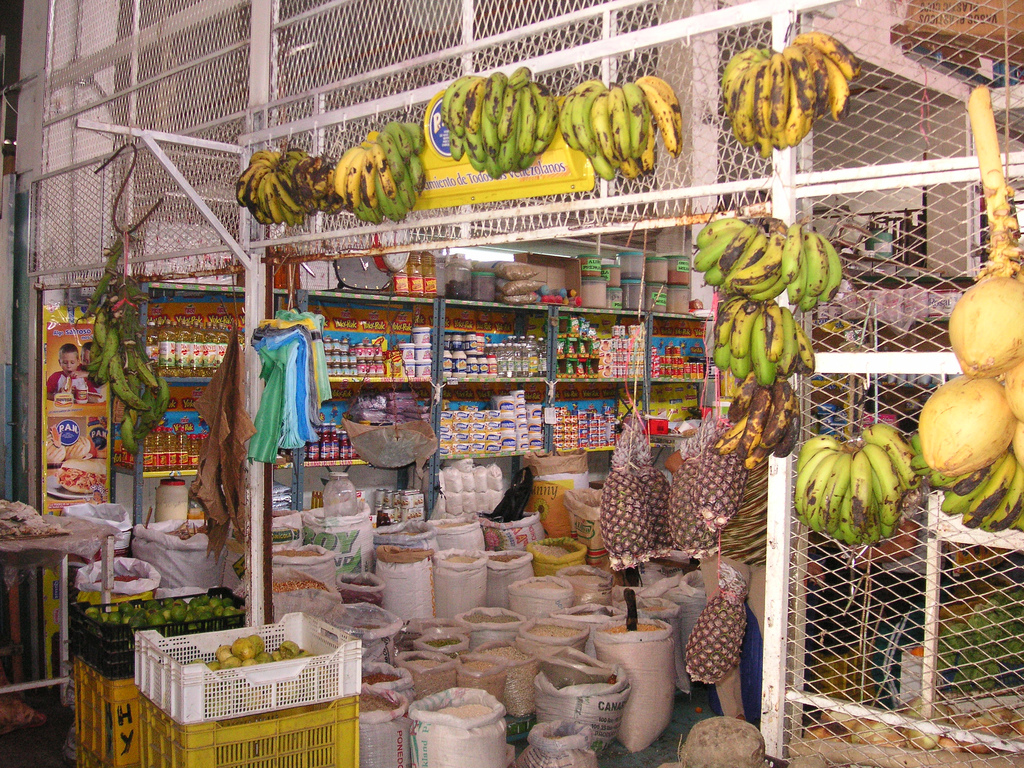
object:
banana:
[722, 32, 862, 158]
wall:
[19, 0, 120, 282]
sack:
[408, 685, 503, 767]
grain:
[429, 702, 497, 720]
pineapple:
[600, 418, 672, 570]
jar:
[578, 276, 608, 310]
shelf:
[110, 281, 710, 536]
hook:
[88, 176, 164, 272]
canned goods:
[555, 404, 582, 450]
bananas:
[332, 124, 428, 223]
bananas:
[444, 65, 559, 178]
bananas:
[562, 78, 686, 182]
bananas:
[690, 217, 841, 310]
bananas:
[236, 148, 308, 228]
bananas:
[799, 429, 912, 551]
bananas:
[907, 427, 1024, 533]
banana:
[822, 236, 844, 313]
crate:
[120, 686, 359, 768]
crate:
[69, 585, 249, 680]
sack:
[591, 612, 674, 754]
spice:
[608, 621, 662, 635]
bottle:
[151, 423, 167, 474]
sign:
[413, 183, 597, 305]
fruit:
[169, 603, 189, 625]